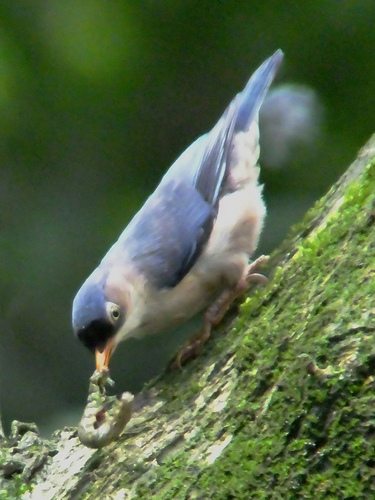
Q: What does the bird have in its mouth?
A: A bug.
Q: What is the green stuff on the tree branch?
A: Moss.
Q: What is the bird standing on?
A: A tree.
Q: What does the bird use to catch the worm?
A: Beak.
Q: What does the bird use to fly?
A: Wings.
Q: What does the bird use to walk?
A: Legs.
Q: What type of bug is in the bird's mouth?
A: A worm.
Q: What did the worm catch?
A: A worm.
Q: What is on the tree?
A: Moss.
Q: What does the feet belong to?
A: A bird.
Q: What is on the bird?
A: Feathers.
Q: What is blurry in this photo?
A: The background.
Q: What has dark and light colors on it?
A: A bird.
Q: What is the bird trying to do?
A: Eat a worm.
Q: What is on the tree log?
A: A blue bird.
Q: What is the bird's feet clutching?
A: A tree trunk.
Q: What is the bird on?
A: A tree.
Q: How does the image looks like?
A: Good.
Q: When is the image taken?
A: When bird is awake.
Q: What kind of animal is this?
A: A bird.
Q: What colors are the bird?
A: Blue and white.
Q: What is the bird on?
A: A log.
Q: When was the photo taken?
A: Daytime.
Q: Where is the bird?
A: On a log.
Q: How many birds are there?
A: One.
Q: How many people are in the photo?
A: None.